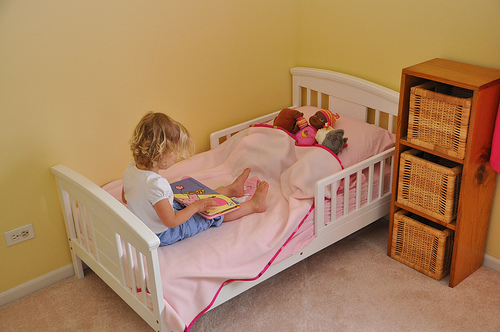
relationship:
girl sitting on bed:
[120, 111, 270, 247] [50, 65, 399, 331]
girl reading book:
[120, 111, 270, 247] [167, 177, 239, 219]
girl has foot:
[120, 111, 270, 247] [249, 177, 270, 212]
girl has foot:
[120, 111, 270, 247] [232, 165, 252, 197]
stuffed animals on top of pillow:
[269, 106, 348, 157] [264, 102, 397, 176]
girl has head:
[120, 111, 270, 247] [128, 109, 193, 170]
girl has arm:
[120, 111, 270, 247] [154, 195, 198, 230]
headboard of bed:
[287, 66, 400, 138] [50, 65, 399, 331]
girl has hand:
[120, 111, 270, 247] [193, 197, 217, 213]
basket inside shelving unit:
[391, 210, 454, 281] [385, 57, 499, 288]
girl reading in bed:
[120, 111, 270, 247] [50, 65, 399, 331]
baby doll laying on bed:
[292, 106, 339, 150] [50, 65, 399, 331]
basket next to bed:
[407, 80, 472, 158] [50, 65, 399, 331]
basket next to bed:
[394, 148, 462, 224] [50, 65, 399, 331]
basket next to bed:
[387, 208, 455, 281] [50, 65, 399, 331]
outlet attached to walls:
[3, 222, 36, 247] [1, 0, 499, 294]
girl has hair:
[120, 111, 270, 247] [128, 111, 194, 170]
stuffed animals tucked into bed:
[269, 106, 348, 157] [50, 65, 399, 331]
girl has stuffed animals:
[120, 111, 270, 247] [269, 106, 348, 157]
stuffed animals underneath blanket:
[269, 106, 348, 157] [75, 123, 345, 330]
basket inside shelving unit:
[407, 80, 472, 158] [385, 57, 499, 288]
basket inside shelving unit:
[394, 148, 462, 224] [385, 57, 499, 288]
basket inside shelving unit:
[387, 208, 455, 281] [385, 57, 499, 288]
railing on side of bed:
[313, 145, 395, 244] [50, 65, 399, 331]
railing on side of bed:
[207, 105, 297, 151] [50, 65, 399, 331]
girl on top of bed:
[120, 111, 270, 247] [50, 65, 399, 331]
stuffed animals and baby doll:
[269, 106, 348, 157] [292, 106, 339, 150]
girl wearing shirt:
[120, 111, 270, 247] [121, 163, 175, 233]